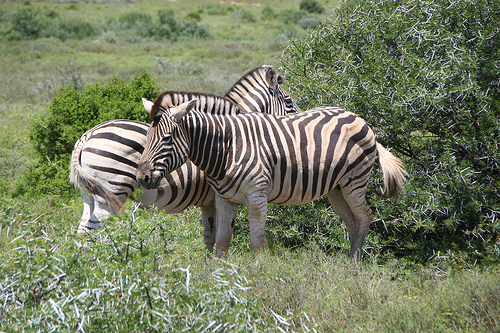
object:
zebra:
[134, 98, 411, 261]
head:
[135, 91, 198, 190]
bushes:
[0, 0, 212, 40]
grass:
[1, 1, 227, 84]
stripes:
[244, 113, 342, 201]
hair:
[148, 91, 242, 122]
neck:
[183, 108, 234, 180]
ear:
[168, 98, 198, 122]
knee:
[354, 209, 375, 230]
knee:
[215, 225, 232, 248]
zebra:
[66, 64, 303, 252]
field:
[0, 0, 500, 333]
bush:
[0, 199, 311, 333]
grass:
[1, 196, 500, 333]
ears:
[141, 97, 154, 115]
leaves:
[301, 40, 353, 100]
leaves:
[410, 199, 444, 232]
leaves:
[410, 100, 443, 142]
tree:
[232, 0, 499, 270]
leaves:
[471, 51, 500, 126]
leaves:
[384, 18, 464, 98]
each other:
[68, 64, 408, 263]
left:
[136, 90, 409, 262]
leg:
[244, 174, 271, 249]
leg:
[339, 170, 375, 256]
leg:
[213, 199, 236, 257]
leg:
[325, 184, 358, 240]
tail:
[376, 140, 411, 199]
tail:
[68, 120, 126, 214]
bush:
[274, 0, 499, 264]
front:
[136, 96, 244, 204]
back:
[78, 142, 140, 234]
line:
[0, 0, 222, 44]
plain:
[0, 0, 500, 333]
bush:
[9, 70, 167, 203]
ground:
[1, 1, 299, 331]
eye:
[159, 134, 172, 142]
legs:
[201, 203, 218, 250]